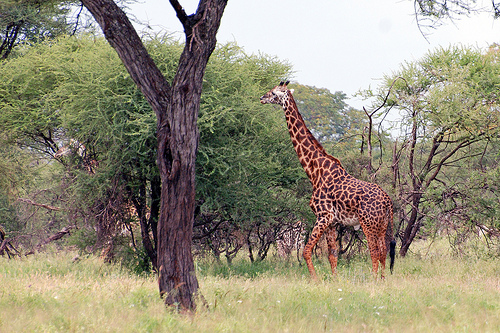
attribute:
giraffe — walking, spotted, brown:
[257, 76, 399, 288]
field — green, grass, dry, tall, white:
[1, 236, 500, 333]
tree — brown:
[376, 42, 500, 268]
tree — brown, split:
[80, 4, 238, 315]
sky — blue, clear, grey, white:
[2, 1, 499, 147]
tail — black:
[385, 197, 402, 279]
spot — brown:
[306, 158, 318, 173]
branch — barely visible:
[407, 0, 500, 46]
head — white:
[256, 77, 296, 108]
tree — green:
[2, 32, 316, 268]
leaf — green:
[206, 119, 215, 131]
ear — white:
[287, 88, 298, 98]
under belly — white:
[333, 215, 361, 230]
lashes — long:
[270, 89, 277, 98]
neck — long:
[283, 96, 338, 182]